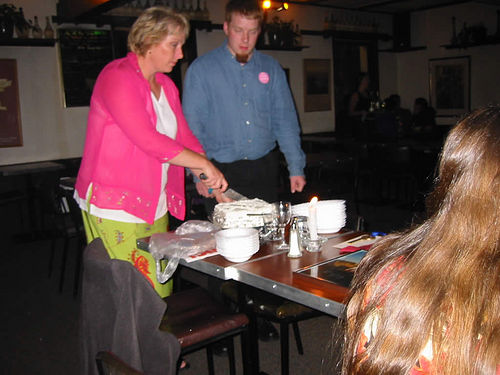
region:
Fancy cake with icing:
[213, 197, 272, 229]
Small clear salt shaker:
[287, 222, 302, 260]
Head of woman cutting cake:
[126, 7, 188, 78]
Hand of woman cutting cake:
[193, 158, 232, 195]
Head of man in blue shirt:
[221, 2, 263, 60]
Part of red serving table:
[264, 257, 286, 276]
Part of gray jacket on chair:
[88, 270, 131, 315]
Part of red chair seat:
[177, 297, 214, 322]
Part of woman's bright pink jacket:
[107, 139, 131, 187]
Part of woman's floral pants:
[107, 227, 133, 250]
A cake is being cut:
[15, 1, 481, 356]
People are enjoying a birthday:
[16, 10, 476, 362]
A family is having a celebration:
[20, 12, 475, 365]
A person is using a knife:
[35, 7, 456, 372]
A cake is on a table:
[21, 2, 458, 372]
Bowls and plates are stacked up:
[27, 10, 473, 367]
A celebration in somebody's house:
[15, 5, 473, 367]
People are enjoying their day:
[38, 2, 471, 372]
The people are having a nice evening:
[13, 12, 489, 365]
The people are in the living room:
[20, 8, 492, 368]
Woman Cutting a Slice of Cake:
[70, 3, 247, 238]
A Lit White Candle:
[293, 191, 335, 257]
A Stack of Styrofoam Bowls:
[208, 224, 267, 267]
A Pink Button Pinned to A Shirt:
[243, 63, 289, 108]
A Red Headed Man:
[218, 0, 281, 92]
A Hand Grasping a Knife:
[187, 159, 270, 206]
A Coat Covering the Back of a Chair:
[58, 224, 253, 367]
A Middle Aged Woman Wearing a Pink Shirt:
[64, 5, 197, 237]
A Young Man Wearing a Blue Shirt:
[190, 0, 312, 198]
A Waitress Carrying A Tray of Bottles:
[335, 60, 435, 135]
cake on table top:
[202, 196, 279, 235]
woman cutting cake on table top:
[75, 0, 285, 374]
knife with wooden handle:
[196, 169, 251, 202]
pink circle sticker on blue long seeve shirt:
[254, 69, 273, 86]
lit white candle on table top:
[302, 192, 327, 256]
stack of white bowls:
[209, 224, 262, 266]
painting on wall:
[296, 52, 337, 117]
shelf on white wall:
[3, 2, 59, 57]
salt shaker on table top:
[286, 221, 306, 260]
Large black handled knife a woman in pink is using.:
[198, 172, 250, 202]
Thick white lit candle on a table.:
[306, 196, 321, 238]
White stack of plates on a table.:
[288, 196, 347, 236]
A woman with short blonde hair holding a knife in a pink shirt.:
[73, 5, 229, 371]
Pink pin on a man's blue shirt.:
[257, 69, 269, 83]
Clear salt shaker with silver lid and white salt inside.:
[287, 224, 302, 259]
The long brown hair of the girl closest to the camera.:
[341, 108, 498, 371]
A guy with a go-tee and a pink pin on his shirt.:
[186, 0, 306, 354]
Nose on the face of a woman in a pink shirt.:
[174, 44, 183, 61]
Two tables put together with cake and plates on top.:
[133, 228, 398, 322]